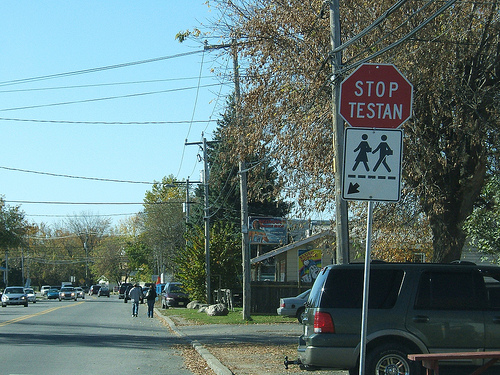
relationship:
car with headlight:
[58, 277, 80, 300] [72, 291, 79, 298]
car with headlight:
[58, 277, 80, 300] [60, 291, 66, 296]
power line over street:
[0, 195, 190, 205] [1, 295, 191, 371]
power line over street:
[0, 161, 183, 189] [1, 295, 191, 371]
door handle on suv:
[409, 312, 432, 325] [289, 260, 499, 372]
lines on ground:
[21, 291, 89, 339] [0, 291, 295, 373]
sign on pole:
[321, 55, 452, 309] [358, 198, 378, 373]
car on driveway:
[284, 258, 499, 373] [170, 320, 321, 340]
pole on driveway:
[198, 133, 216, 305] [170, 320, 321, 340]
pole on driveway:
[181, 174, 193, 304] [170, 320, 321, 340]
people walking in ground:
[122, 279, 161, 320] [0, 291, 295, 373]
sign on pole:
[339, 55, 413, 131] [354, 204, 378, 374]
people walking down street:
[142, 284, 158, 318] [0, 303, 182, 373]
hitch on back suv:
[281, 352, 306, 370] [287, 253, 497, 369]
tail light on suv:
[311, 307, 338, 341] [289, 260, 499, 372]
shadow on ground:
[1, 317, 297, 354] [0, 291, 295, 373]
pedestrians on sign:
[357, 133, 392, 179] [339, 124, 407, 206]